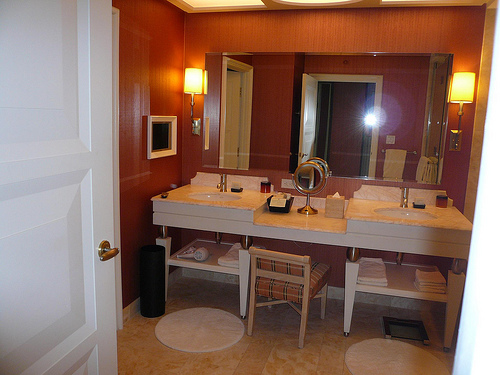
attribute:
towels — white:
[414, 270, 446, 294]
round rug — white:
[152, 302, 242, 352]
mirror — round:
[179, 37, 456, 221]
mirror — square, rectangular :
[200, 53, 450, 189]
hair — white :
[175, 244, 216, 261]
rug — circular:
[152, 306, 244, 356]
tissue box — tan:
[322, 192, 347, 221]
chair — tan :
[260, 240, 357, 338]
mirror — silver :
[200, 47, 461, 177]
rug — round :
[333, 322, 450, 374]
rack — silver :
[380, 146, 420, 158]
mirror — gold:
[290, 147, 342, 217]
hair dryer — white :
[168, 242, 208, 264]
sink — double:
[380, 200, 415, 225]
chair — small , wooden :
[241, 242, 331, 352]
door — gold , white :
[0, 2, 119, 372]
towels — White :
[348, 252, 451, 301]